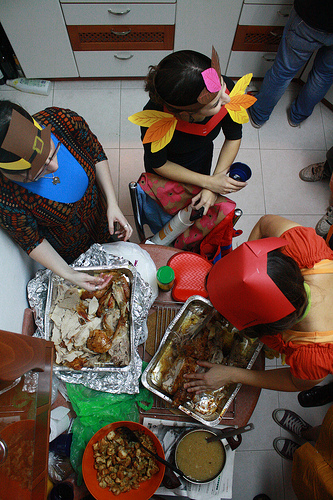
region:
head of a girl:
[143, 45, 234, 114]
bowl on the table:
[75, 414, 168, 487]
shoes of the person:
[254, 396, 319, 465]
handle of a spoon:
[107, 416, 143, 447]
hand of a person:
[170, 347, 236, 403]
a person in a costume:
[139, 45, 256, 222]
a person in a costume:
[4, 127, 143, 283]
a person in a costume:
[215, 211, 332, 412]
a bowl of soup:
[175, 425, 232, 486]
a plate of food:
[84, 431, 154, 496]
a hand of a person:
[147, 129, 258, 215]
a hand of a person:
[13, 219, 121, 315]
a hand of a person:
[76, 121, 141, 242]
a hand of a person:
[184, 339, 327, 412]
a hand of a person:
[186, 109, 262, 217]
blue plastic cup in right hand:
[206, 158, 254, 196]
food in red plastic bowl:
[80, 417, 167, 499]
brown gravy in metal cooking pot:
[170, 429, 235, 487]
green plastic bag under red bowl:
[62, 389, 147, 453]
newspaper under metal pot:
[162, 421, 246, 498]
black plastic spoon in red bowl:
[117, 421, 189, 479]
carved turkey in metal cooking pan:
[40, 264, 139, 372]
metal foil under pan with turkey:
[31, 242, 147, 396]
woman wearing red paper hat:
[206, 231, 297, 339]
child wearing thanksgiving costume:
[124, 45, 262, 158]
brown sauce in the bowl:
[174, 428, 226, 495]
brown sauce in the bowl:
[162, 413, 234, 492]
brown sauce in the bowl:
[181, 437, 235, 492]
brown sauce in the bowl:
[175, 435, 224, 489]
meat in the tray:
[44, 266, 148, 394]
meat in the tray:
[53, 273, 145, 396]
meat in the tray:
[44, 253, 130, 378]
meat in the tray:
[47, 271, 133, 376]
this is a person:
[115, 52, 254, 215]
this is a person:
[2, 104, 141, 290]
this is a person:
[182, 209, 330, 403]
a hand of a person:
[59, 116, 140, 248]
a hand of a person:
[138, 129, 264, 213]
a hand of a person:
[184, 121, 253, 218]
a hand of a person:
[188, 342, 331, 408]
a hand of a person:
[239, 199, 315, 255]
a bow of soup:
[168, 430, 237, 490]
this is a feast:
[70, 277, 258, 477]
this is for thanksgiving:
[37, 148, 226, 465]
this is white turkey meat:
[41, 252, 143, 361]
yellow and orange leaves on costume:
[135, 107, 179, 154]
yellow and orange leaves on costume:
[228, 65, 259, 129]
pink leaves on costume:
[195, 47, 224, 98]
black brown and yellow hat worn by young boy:
[7, 112, 52, 186]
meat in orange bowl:
[93, 423, 150, 490]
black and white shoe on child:
[276, 407, 302, 432]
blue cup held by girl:
[226, 153, 250, 188]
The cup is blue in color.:
[229, 162, 252, 183]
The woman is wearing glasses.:
[1, 97, 62, 188]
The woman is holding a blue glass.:
[128, 47, 258, 213]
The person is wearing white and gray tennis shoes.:
[269, 408, 313, 462]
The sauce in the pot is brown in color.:
[172, 428, 227, 482]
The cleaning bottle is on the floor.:
[4, 77, 55, 95]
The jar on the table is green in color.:
[156, 263, 176, 292]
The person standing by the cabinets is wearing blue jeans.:
[247, 0, 331, 144]